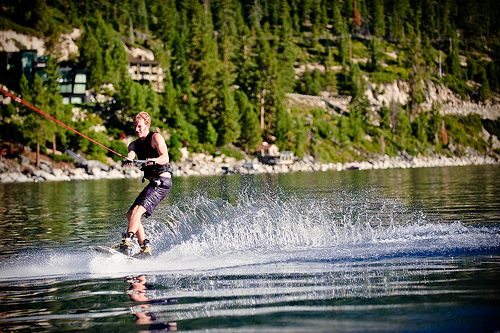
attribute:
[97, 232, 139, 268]
ski — water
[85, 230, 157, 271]
skiing — water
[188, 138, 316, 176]
shore — rocky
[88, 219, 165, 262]
skiing — water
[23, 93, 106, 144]
line — orange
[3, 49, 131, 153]
building — by shore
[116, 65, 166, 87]
wooden deck — on house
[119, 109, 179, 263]
man skiing — leaving waves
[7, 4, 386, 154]
pine trees — on hill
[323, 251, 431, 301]
ripples — on water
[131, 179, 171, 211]
man — wearing shorts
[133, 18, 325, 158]
pine trees — forest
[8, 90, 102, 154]
tether cord — red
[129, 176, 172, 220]
swim trunks — mens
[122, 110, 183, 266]
man — wearing safety vest, wearing swim trunks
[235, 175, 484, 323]
large body — water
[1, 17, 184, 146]
houses — blocked by trees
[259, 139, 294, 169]
small house — on the water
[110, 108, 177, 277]
man — on water skis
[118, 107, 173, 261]
man — water skiing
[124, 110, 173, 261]
man — water skiing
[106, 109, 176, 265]
man — holding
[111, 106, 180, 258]
man — water skiing, surfing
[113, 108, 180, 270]
person — reflected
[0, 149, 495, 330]
water — splashing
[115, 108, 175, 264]
surfer — holding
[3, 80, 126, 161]
rope — red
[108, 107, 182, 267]
person — blonde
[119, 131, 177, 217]
clothes — black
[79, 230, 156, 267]
surfboard — white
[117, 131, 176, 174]
top — black